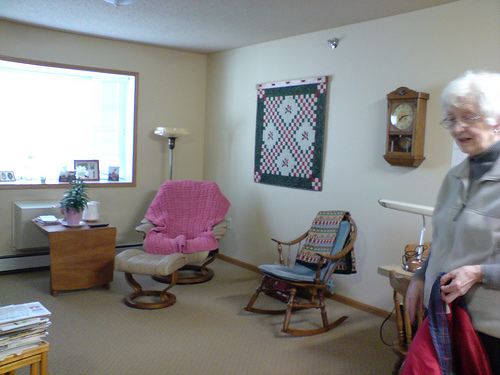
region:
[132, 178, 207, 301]
that is a chair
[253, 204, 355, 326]
that is a chair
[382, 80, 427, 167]
that is a wall clock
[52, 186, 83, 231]
flowers in a vase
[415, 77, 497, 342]
this is an old woman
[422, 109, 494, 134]
the lady is wearing spectacles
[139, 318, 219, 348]
the floor of the room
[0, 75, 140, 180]
that is a window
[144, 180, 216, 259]
pink cloth spread on the chair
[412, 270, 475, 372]
the woman is carrying a jacket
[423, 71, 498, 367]
A woman with grey hair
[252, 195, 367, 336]
A brown wooden rocking chair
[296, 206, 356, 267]
A blanket on back of rocking chair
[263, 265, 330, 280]
Blue cushion in rocking chair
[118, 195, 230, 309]
A rocking swivel rocking chair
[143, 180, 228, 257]
A pink knit blanket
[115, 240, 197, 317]
A foot stool with beige cushion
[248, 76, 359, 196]
A quilted wall hanging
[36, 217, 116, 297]
A light brown wooden table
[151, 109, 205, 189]
A lamp behind the rocking chair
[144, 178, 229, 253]
a pink knitted blanket on a chair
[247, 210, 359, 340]
a wooden rocking chair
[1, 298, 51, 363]
a stack of papers on a table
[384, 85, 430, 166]
a wooden clock on the wall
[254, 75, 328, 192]
a painting on the wall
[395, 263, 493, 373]
a woman carrying a scarf and coat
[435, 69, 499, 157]
a woman with white hair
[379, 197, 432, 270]
a lamp on a desk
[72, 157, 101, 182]
a frame on the windowsill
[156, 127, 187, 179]
a standing lamp in the corner of a living room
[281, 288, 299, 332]
brown wooden chair leg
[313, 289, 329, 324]
brown wooden chair leg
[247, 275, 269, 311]
brown wooden chair leg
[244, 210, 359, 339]
brown wooden rocking chair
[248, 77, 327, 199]
blanket hanging on wall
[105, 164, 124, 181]
picture on window sill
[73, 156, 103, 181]
picture on window sill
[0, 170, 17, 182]
picture on window sill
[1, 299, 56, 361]
stack of white papers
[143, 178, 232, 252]
pink blanket on chair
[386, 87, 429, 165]
a wood clock on wall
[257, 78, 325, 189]
a colorful hanging on wall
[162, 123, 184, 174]
part of pole lamp behind chair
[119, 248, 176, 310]
a cloth covered ottoman with wood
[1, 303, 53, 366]
a stack of mail on table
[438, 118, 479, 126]
eye glasses on woman's face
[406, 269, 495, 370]
woman's hand holding jacket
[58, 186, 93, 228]
plant in white vase on stand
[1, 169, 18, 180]
a framed picture on window shelf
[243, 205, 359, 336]
a blue rocking chair in room